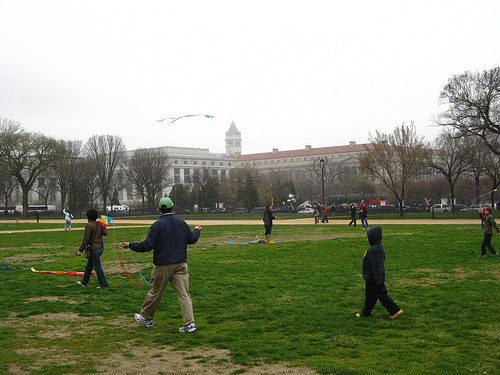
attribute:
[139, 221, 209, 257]
jacket — blue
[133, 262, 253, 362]
pants — tan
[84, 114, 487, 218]
building — large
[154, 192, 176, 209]
cap — green 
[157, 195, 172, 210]
cap — green, baseball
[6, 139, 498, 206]
buildings — large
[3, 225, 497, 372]
grass — green 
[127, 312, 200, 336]
shoes — white, blue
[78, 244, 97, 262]
purse — black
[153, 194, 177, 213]
cap — green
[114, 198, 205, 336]
kite flyers — successful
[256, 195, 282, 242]
kite flyers — successful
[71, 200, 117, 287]
kite flyers — successful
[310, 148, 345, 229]
lamp post — black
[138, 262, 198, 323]
pants — khaki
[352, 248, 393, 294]
shirt — black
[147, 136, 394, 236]
building — white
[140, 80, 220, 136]
kite — long 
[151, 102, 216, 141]
kite — flying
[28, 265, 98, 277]
kite tail — long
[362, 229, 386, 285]
hoodie — navy blue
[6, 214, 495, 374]
field — large, city, grass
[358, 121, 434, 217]
tree — green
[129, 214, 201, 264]
jacket — blue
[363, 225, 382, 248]
hood — up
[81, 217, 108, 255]
jacket — brown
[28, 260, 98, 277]
kite — rainbow